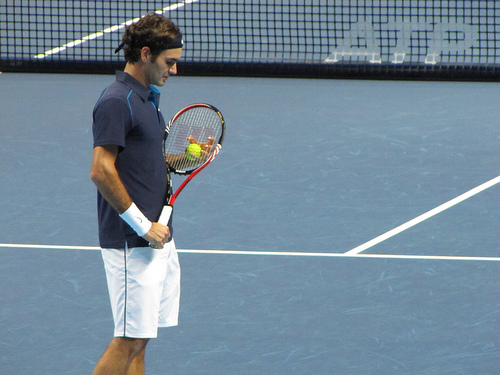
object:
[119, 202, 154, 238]
band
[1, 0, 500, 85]
tennis net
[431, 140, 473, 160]
ground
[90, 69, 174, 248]
polo shirt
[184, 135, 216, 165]
hand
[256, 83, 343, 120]
ground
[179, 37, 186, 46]
design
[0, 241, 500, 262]
line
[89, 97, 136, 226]
arm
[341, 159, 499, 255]
lines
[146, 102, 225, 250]
racket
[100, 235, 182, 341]
shorts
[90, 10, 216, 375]
man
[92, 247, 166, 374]
leg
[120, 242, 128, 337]
stripe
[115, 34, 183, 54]
fabric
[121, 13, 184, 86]
head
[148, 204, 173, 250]
handle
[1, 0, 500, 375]
court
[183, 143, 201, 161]
ball